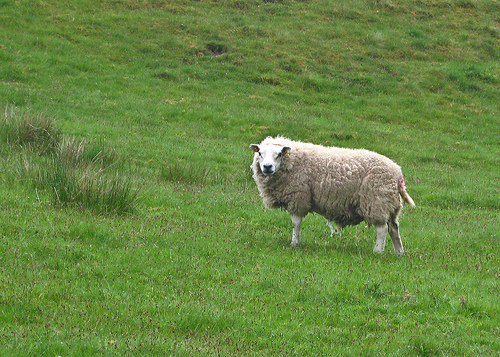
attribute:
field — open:
[6, 5, 492, 350]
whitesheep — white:
[250, 122, 417, 259]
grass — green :
[126, 225, 318, 352]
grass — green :
[1, 0, 498, 352]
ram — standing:
[235, 127, 422, 258]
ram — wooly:
[251, 134, 416, 254]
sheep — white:
[196, 111, 443, 290]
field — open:
[74, 96, 495, 352]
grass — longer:
[39, 180, 206, 321]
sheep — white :
[251, 130, 417, 255]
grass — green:
[398, 79, 480, 116]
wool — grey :
[253, 135, 417, 227]